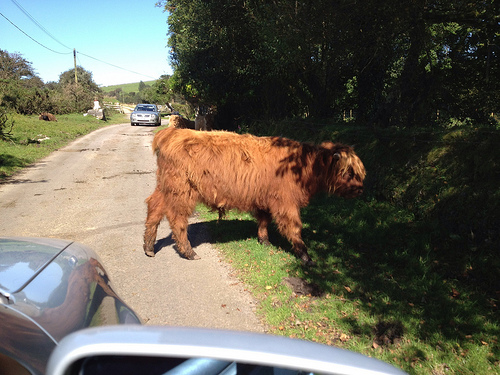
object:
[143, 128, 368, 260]
cow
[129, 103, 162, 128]
car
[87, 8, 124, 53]
sky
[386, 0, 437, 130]
tree